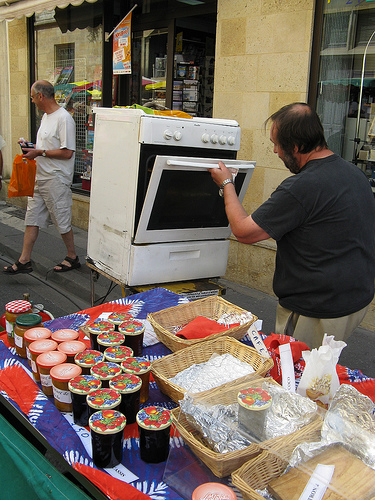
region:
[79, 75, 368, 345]
A man inspecting an oven.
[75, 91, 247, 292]
A stove is on top of a metal structure.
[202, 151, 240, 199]
The man is wearing a watch on his left wrist.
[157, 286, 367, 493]
Four baskets with different items in them.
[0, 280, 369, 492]
A red and blue table cloth is on the table.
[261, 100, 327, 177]
The man has a beard.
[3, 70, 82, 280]
The man is walking out of a store.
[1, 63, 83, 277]
The man has his wallet in his hands.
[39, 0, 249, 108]
A store.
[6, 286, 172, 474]
Several jars of jam.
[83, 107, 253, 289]
an old oven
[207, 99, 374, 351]
a man opening up the door of an old oven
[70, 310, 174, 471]
jars of preserves with pretty labels on them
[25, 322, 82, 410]
jars of nut butter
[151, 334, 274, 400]
a wicker basket with something shiny inside of it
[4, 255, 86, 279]
a man's sandals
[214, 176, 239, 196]
a man's wrist watch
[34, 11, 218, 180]
a store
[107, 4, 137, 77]
a store's advertising banner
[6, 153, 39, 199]
an orange plastic bag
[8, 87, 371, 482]
Outdoor farmer's market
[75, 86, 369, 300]
Man opening up the oven door.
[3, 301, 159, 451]
Jars of fruit jelly.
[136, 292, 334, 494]
There are wicker baskets on the table.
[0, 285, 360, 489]
The table cloth has a tie-dye pattern.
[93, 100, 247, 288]
The stove is white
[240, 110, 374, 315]
The man is wearing a black t-shirt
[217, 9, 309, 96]
The storefront in the background has natural stone siding.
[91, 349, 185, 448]
The jelly jars have floral decorative lids.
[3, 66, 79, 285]
The man in the background is carrying an orange bag.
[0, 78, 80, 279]
man is late middle-aged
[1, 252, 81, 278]
middle aged man wears neva sandals or maybe birkenstocks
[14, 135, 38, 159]
middle aged man carries open wallet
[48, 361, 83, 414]
homemade preserves, probably apricot or marmalade, in ball jar with orange lid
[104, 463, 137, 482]
sign beneath dark red homemade jam reads 'cassis', its flavor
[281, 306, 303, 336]
middle aged man wears beige pants with large open pocket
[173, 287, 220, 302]
rickety table holding stove has bumper sticker pasted to it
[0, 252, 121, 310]
electrical cord for stove leads off into the distance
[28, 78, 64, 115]
middle aged man looks pleasant despite grey & disappearing hair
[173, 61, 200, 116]
rack carries maps & many sizes of postcard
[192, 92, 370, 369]
Man opening an oven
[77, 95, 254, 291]
A white stove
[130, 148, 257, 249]
Door of oven is windowed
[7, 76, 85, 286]
Man holding a plastic bag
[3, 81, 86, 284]
Man wearing brown sandals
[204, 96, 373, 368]
Man wears a black shirt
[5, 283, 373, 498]
Jars of food on a table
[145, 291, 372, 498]
Five baskets next to jars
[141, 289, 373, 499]
Aluminium paper covering the bottom of baskets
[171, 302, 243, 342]
Red napkin on a basket